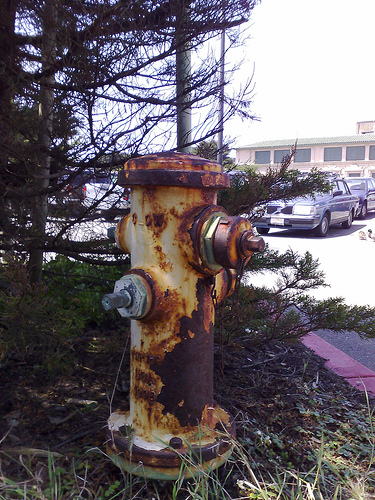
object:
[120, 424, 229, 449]
bolts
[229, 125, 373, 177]
building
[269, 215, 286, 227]
licence plate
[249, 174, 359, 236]
car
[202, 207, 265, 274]
valve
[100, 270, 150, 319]
valve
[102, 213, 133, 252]
valve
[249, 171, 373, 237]
cars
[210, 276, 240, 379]
chain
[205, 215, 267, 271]
plug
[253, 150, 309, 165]
window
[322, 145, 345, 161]
window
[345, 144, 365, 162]
window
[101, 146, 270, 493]
fire hydrant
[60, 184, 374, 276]
road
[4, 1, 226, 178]
trees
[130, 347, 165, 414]
letters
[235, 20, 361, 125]
sky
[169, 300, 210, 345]
rust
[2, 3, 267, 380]
tree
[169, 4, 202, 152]
poles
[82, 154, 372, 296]
parking lot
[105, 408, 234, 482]
bottom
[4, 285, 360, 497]
ground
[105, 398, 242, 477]
base